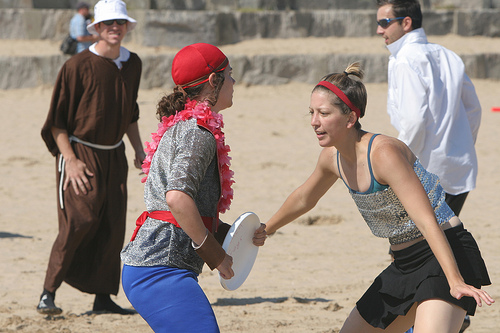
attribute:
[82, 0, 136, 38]
hat — white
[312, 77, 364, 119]
headband — red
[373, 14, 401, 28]
sunglasses — dark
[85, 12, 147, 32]
sunglass — pair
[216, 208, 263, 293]
frisbee — white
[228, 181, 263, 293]
frisbee — white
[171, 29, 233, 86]
cap — tight, red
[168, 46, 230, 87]
stocking cap — red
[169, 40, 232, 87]
cap — red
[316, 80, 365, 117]
band — red, head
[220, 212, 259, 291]
frisbee — white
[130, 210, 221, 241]
belt — red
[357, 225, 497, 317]
skirt — black